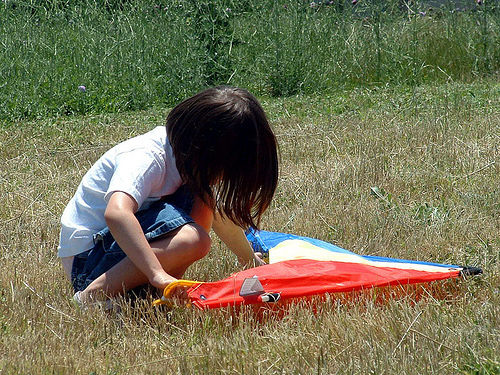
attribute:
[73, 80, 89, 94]
flower — purple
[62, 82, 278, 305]
girl — little, young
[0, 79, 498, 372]
grass — long, brown, tall, green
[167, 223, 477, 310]
kite — multicolored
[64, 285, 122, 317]
sneaker — white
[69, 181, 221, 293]
skirt — blue jean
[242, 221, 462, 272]
section — blue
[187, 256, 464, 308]
section — red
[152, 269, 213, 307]
holder — yellow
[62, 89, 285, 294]
girl — young